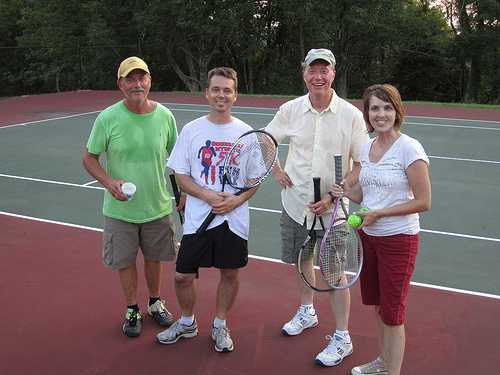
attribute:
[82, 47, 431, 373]
people — posing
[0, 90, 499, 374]
tennis court — green, red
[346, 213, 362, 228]
tennis ball — yellow, green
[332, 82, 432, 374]
woman — standing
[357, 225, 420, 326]
shorts — red, black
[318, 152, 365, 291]
racket — pink, white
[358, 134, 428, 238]
top — white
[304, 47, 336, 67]
hat — green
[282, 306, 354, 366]
shoes — white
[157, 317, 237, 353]
shoes — white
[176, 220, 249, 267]
shorts — black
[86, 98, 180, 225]
shirt — green, short sleeved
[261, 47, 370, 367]
man — smiling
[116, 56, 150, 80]
hat — yellow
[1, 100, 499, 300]
lines — white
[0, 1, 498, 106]
trees — green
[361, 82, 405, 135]
hair — brown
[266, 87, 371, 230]
shirt — yellow